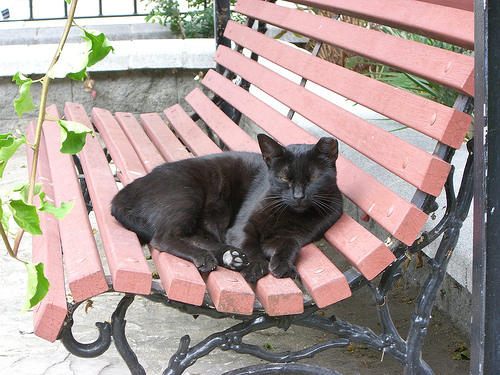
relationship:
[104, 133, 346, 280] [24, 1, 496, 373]
cat on bench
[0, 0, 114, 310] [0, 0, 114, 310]
branch on a branch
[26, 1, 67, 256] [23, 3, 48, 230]
stem of plant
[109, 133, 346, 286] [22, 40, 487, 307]
cat sitting on a bench